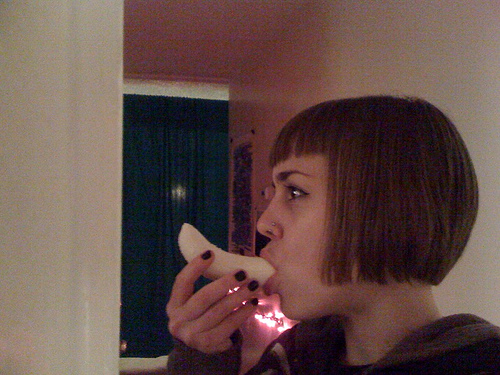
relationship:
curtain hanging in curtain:
[118, 93, 231, 358] [118, 93, 231, 358]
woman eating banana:
[165, 95, 500, 375] [176, 223, 274, 283]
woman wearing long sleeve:
[152, 82, 496, 374] [164, 332, 239, 372]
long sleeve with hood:
[164, 332, 239, 372] [298, 311, 498, 361]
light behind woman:
[226, 282, 292, 332] [152, 30, 499, 373]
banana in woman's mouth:
[173, 216, 278, 291] [260, 247, 278, 291]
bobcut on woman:
[268, 92, 478, 287] [152, 82, 496, 374]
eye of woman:
[287, 185, 309, 202] [152, 82, 496, 374]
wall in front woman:
[1, 3, 118, 370] [158, 52, 475, 374]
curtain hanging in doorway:
[124, 94, 234, 357] [127, 79, 227, 370]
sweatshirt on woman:
[162, 309, 495, 369] [206, 95, 483, 297]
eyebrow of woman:
[274, 167, 311, 183] [152, 82, 496, 374]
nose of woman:
[252, 182, 287, 240] [152, 82, 496, 374]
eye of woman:
[285, 181, 306, 198] [152, 82, 496, 374]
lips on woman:
[257, 247, 277, 298] [152, 82, 496, 374]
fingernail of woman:
[201, 250, 211, 259] [152, 82, 496, 374]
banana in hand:
[178, 223, 278, 288] [159, 250, 259, 373]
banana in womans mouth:
[173, 216, 278, 291] [252, 245, 283, 299]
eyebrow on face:
[274, 167, 311, 183] [256, 153, 329, 322]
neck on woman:
[343, 280, 442, 365] [216, 86, 486, 345]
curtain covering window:
[118, 93, 231, 358] [119, 72, 316, 370]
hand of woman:
[151, 289, 248, 363] [254, 126, 466, 361]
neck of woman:
[345, 278, 442, 365] [152, 82, 496, 374]